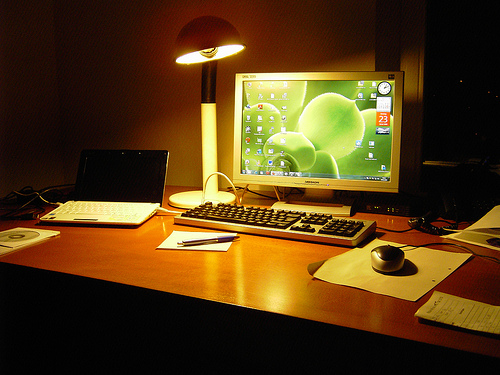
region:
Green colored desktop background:
[241, 78, 393, 183]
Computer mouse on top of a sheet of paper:
[306, 233, 475, 303]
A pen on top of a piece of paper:
[153, 228, 241, 253]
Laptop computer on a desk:
[36, 146, 173, 228]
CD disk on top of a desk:
[0, 225, 62, 255]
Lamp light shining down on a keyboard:
[166, 13, 249, 210]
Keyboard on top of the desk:
[171, 199, 379, 249]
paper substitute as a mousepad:
[305, 233, 475, 304]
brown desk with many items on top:
[0, 178, 499, 365]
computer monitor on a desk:
[231, 70, 405, 220]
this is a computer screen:
[220, 55, 405, 200]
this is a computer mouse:
[366, 245, 396, 291]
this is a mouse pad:
[315, 235, 470, 310]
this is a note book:
[417, 290, 492, 331]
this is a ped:
[170, 231, 237, 256]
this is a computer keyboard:
[178, 185, 373, 271]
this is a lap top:
[41, 141, 166, 247]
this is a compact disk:
[2, 220, 54, 266]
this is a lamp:
[160, 2, 235, 192]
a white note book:
[161, 227, 238, 270]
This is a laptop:
[35, 135, 172, 232]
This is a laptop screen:
[62, 137, 168, 202]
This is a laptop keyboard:
[47, 195, 162, 230]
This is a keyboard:
[170, 181, 390, 256]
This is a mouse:
[360, 235, 420, 280]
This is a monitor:
[225, 65, 410, 190]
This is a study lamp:
[162, 5, 244, 192]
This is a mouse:
[335, 230, 475, 300]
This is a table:
[0, 187, 495, 357]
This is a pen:
[167, 228, 247, 264]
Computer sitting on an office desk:
[174, 69, 403, 249]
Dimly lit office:
[1, 0, 498, 374]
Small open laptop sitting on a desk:
[39, 148, 168, 227]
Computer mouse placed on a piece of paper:
[308, 235, 473, 302]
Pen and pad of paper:
[152, 228, 239, 252]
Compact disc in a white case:
[1, 223, 61, 262]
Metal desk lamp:
[167, 15, 246, 205]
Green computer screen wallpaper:
[240, 79, 392, 180]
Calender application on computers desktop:
[375, 95, 392, 133]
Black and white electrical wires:
[1, 173, 283, 214]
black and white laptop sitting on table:
[32, 132, 177, 227]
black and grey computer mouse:
[367, 238, 423, 285]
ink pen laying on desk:
[169, 231, 257, 250]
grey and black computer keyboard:
[174, 192, 377, 250]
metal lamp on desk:
[161, 11, 240, 197]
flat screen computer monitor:
[226, 68, 419, 195]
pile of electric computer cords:
[1, 171, 53, 217]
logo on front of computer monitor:
[383, 65, 403, 81]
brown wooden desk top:
[64, 229, 152, 289]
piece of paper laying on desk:
[417, 288, 497, 334]